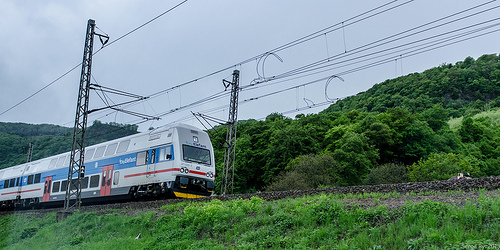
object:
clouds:
[23, 25, 96, 75]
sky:
[0, 0, 500, 132]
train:
[0, 124, 223, 210]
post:
[66, 21, 101, 168]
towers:
[215, 67, 251, 199]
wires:
[242, 10, 500, 91]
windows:
[114, 140, 130, 154]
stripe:
[124, 165, 210, 179]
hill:
[152, 190, 322, 227]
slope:
[34, 124, 76, 147]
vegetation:
[307, 82, 422, 134]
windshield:
[181, 144, 212, 165]